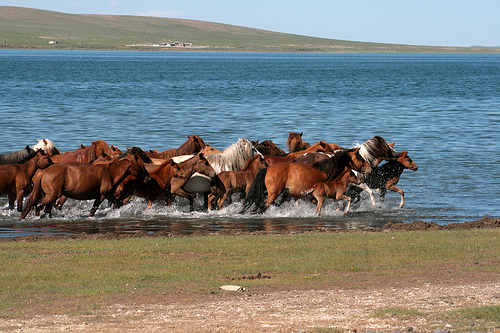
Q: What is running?
A: Horses.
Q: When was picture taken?
A: Daytime.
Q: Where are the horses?
A: In the water.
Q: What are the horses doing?
A: Running.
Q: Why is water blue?
A: Reflecting sky.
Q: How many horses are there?
A: About ten.